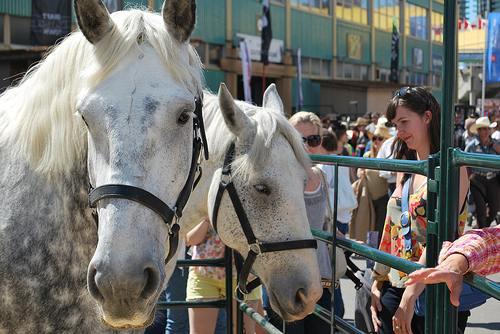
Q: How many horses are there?
A: Two.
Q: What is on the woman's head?
A: Glasses.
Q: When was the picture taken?
A: Daytime.